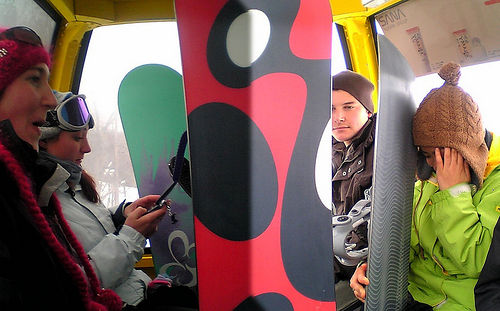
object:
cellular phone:
[145, 179, 182, 216]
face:
[419, 143, 465, 176]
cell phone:
[137, 181, 179, 217]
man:
[330, 68, 379, 283]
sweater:
[0, 139, 128, 310]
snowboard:
[116, 63, 200, 289]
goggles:
[36, 92, 99, 141]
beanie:
[330, 69, 377, 111]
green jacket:
[407, 161, 500, 311]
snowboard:
[166, 0, 339, 310]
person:
[385, 61, 500, 295]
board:
[360, 33, 418, 310]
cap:
[0, 22, 51, 94]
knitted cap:
[30, 85, 80, 140]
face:
[330, 88, 367, 142]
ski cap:
[407, 58, 489, 190]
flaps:
[452, 135, 492, 189]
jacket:
[44, 163, 157, 309]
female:
[0, 24, 126, 310]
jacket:
[327, 115, 377, 272]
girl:
[37, 83, 201, 310]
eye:
[23, 72, 45, 88]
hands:
[120, 202, 173, 236]